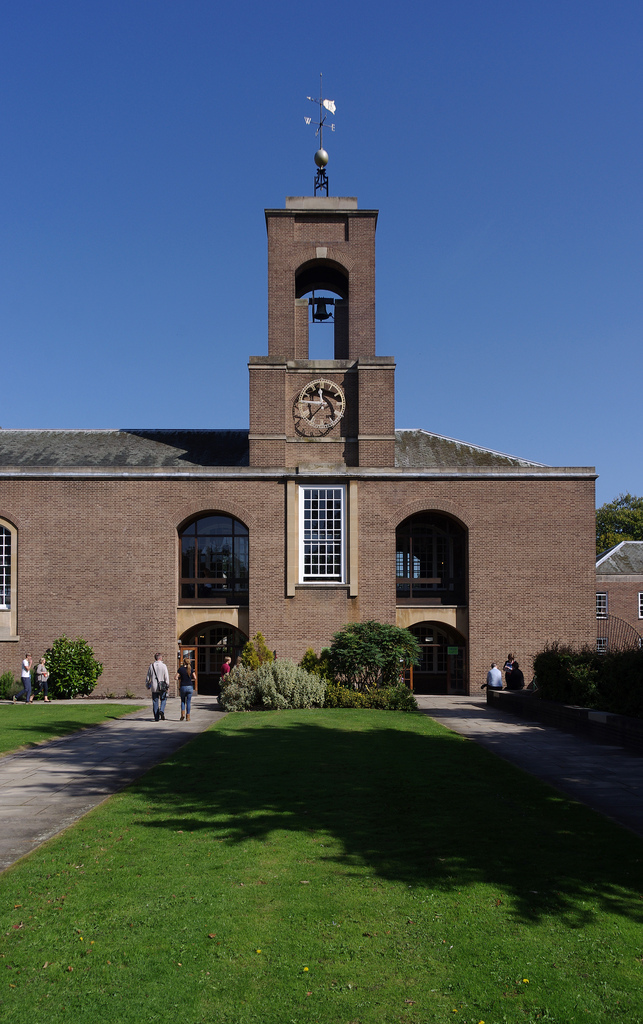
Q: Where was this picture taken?
A: Outside building.